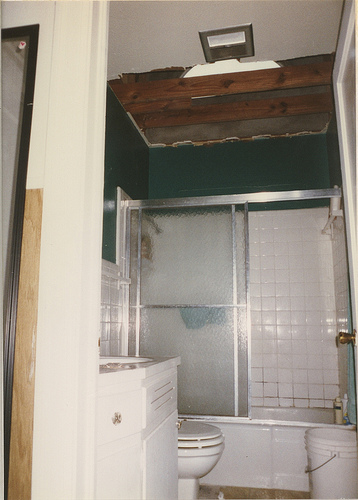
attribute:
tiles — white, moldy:
[245, 208, 345, 409]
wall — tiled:
[148, 133, 343, 411]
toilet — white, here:
[177, 423, 225, 500]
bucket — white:
[305, 427, 357, 500]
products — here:
[333, 394, 348, 424]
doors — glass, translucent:
[126, 205, 252, 420]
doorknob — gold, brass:
[336, 330, 356, 347]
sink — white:
[99, 354, 181, 499]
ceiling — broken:
[109, 1, 343, 150]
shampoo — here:
[332, 393, 348, 426]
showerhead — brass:
[140, 211, 164, 236]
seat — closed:
[178, 421, 224, 451]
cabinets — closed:
[144, 366, 177, 500]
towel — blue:
[179, 306, 230, 330]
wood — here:
[120, 92, 334, 130]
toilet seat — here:
[177, 420, 224, 447]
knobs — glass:
[111, 412, 122, 426]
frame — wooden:
[331, 0, 355, 358]